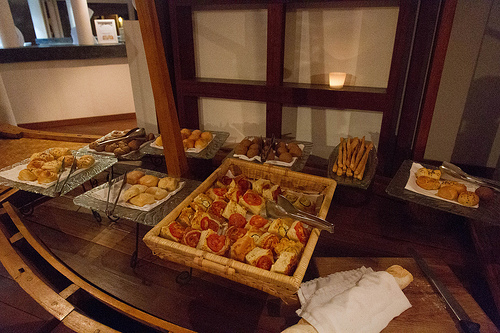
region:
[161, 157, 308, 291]
a tray full of cinnamon rolls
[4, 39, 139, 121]
a counter in the front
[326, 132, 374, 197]
a tray full of snacks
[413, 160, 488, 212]
a tray full of rolls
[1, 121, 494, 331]
a table filled with assorted bread products.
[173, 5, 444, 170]
a window as a decoration on the wall.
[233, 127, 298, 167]
a brown colored bread product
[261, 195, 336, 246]
a pair of tongs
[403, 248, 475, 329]
a long serrated knife to cut bread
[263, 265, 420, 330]
a long loaf of french bread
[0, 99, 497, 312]
Catering bread on table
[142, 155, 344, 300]
Sandwiches in a big wicker basket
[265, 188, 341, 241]
Steel Tong over basket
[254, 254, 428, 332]
French baguette on table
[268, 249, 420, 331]
French baguette is cut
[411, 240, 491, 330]
Big knife with black handle next to French baguette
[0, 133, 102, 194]
Croissants on table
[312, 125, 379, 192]
Bread sticks behind wicker basket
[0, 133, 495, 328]
Side corner fixed to the wall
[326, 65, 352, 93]
Candle is burning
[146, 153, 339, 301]
food is stacked in a basket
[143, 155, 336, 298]
basket is made of wicker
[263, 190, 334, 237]
metal tongs are in the basket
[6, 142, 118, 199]
pastries are stacked on a server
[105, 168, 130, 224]
tongs are in the server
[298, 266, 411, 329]
a towel is laying on the table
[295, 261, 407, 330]
the towel is white in color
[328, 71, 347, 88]
a candle is in the wall shelf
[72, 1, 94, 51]
a column is seen in the background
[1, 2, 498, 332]
the photo was shot indoors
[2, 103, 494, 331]
Buffet on side table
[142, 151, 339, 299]
Sandwiches on a basket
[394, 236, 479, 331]
Knife to cut french bread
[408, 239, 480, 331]
Knife has a black handle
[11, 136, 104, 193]
Croissants on aluminium container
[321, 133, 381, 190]
Bread sticks on a basket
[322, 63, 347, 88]
Candle on a shelf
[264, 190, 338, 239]
Tong on basket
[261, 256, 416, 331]
French baguette cover with a cloth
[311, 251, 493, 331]
Kitchen board under knife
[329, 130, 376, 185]
a plate of breadsticks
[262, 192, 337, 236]
a pair of serving tongs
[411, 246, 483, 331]
a bread knife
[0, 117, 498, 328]
a lunch buffet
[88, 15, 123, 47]
an anoucement sign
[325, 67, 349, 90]
a lit candle in a glass holder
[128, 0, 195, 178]
a wooden pillar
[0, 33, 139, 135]
a counter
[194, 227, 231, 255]
a slice of bread with tomato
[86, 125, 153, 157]
a plate of whole wheat bread